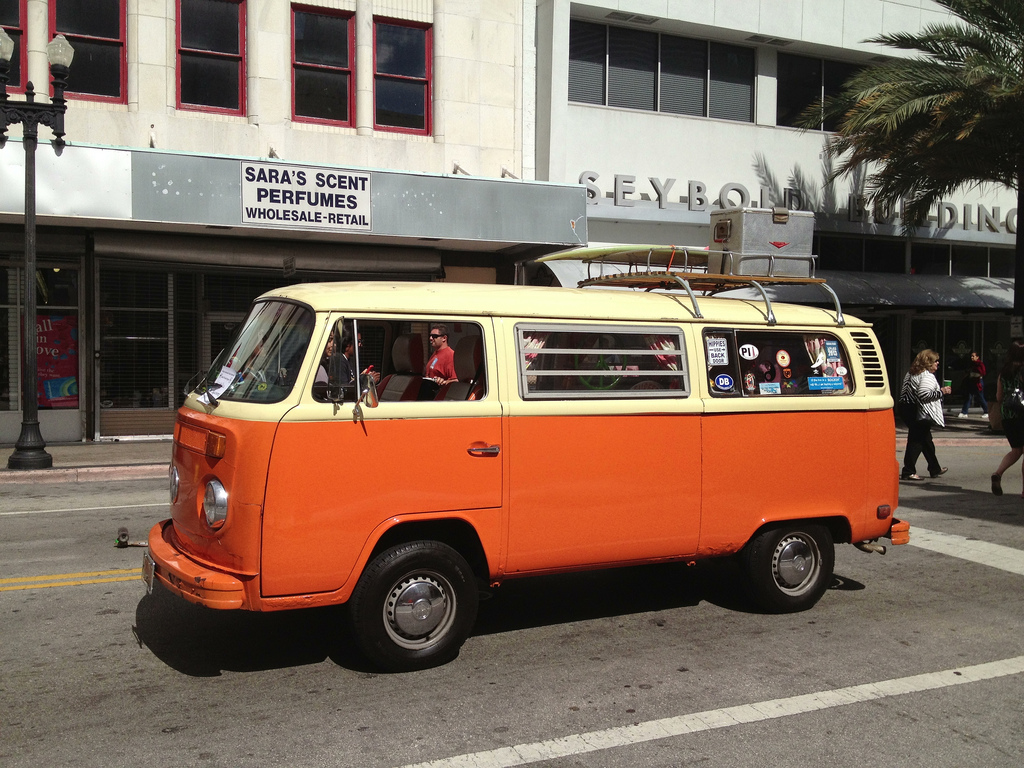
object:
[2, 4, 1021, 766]
outdoors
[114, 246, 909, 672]
van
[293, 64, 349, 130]
glass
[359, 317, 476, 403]
glass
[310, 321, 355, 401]
glass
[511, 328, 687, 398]
glass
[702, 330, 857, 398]
glass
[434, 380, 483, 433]
glass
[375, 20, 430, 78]
glass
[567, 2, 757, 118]
window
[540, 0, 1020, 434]
building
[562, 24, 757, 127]
window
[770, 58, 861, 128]
window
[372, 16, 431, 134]
window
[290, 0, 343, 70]
window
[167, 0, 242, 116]
window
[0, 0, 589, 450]
building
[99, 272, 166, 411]
window